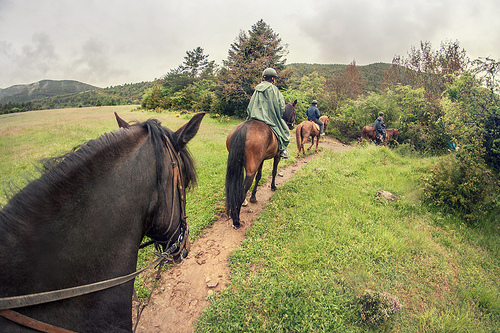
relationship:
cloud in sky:
[1, 30, 134, 96] [0, 0, 500, 95]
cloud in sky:
[283, 2, 455, 65] [0, 0, 500, 95]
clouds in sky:
[369, 19, 387, 28] [5, 6, 498, 102]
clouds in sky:
[326, 12, 413, 43] [130, 12, 197, 37]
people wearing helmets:
[222, 67, 298, 228] [250, 64, 285, 84]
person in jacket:
[244, 65, 291, 158] [244, 81, 289, 150]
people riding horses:
[153, 41, 496, 331] [227, 101, 292, 221]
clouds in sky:
[307, 5, 409, 59] [83, 36, 166, 68]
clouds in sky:
[75, 42, 125, 80] [18, 2, 233, 42]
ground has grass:
[297, 168, 476, 329] [335, 202, 490, 267]